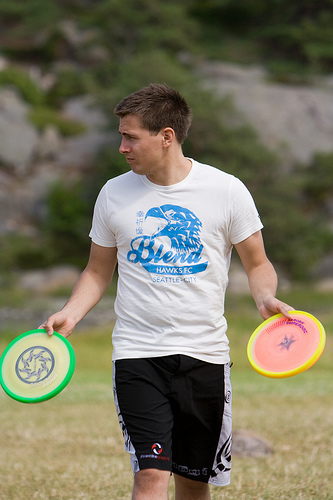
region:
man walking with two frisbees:
[2, 73, 326, 497]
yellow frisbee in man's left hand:
[245, 307, 322, 378]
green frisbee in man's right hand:
[0, 322, 73, 404]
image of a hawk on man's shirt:
[137, 201, 209, 254]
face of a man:
[102, 79, 215, 182]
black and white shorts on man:
[103, 351, 258, 487]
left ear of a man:
[158, 124, 180, 154]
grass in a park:
[275, 389, 322, 496]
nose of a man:
[117, 139, 130, 154]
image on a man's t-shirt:
[124, 201, 216, 290]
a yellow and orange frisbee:
[234, 292, 331, 401]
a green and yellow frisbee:
[6, 321, 85, 412]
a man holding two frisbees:
[4, 134, 331, 425]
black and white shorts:
[79, 311, 277, 498]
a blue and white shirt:
[82, 154, 296, 412]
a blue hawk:
[121, 194, 216, 289]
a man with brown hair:
[58, 83, 299, 333]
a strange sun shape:
[5, 337, 83, 407]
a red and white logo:
[124, 424, 197, 492]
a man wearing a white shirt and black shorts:
[49, 71, 274, 400]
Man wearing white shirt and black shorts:
[26, 87, 305, 498]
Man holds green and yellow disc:
[9, 83, 298, 487]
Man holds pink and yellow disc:
[42, 81, 332, 445]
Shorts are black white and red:
[100, 342, 249, 498]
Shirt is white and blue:
[90, 172, 265, 375]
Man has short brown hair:
[69, 78, 195, 178]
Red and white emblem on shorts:
[133, 432, 173, 469]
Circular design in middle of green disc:
[5, 321, 74, 412]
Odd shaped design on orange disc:
[249, 309, 332, 371]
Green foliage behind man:
[7, 55, 300, 276]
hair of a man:
[140, 87, 165, 115]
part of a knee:
[136, 457, 164, 484]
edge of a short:
[198, 474, 226, 488]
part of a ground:
[269, 428, 304, 460]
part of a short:
[170, 403, 196, 444]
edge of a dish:
[26, 382, 58, 406]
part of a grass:
[282, 430, 321, 469]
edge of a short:
[212, 417, 237, 464]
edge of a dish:
[258, 362, 291, 387]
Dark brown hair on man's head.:
[107, 79, 197, 126]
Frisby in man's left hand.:
[1, 315, 78, 407]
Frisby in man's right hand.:
[236, 292, 331, 382]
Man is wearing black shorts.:
[107, 354, 246, 478]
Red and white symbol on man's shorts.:
[145, 439, 167, 458]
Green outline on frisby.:
[61, 343, 80, 376]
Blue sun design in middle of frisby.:
[11, 343, 57, 387]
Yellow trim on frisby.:
[245, 315, 255, 369]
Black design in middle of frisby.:
[276, 331, 299, 358]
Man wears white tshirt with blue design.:
[112, 188, 232, 366]